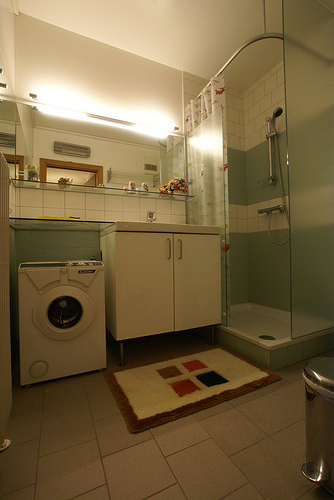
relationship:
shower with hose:
[272, 107, 283, 119] [266, 120, 288, 246]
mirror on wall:
[36, 157, 105, 187] [0, 10, 246, 381]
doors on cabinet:
[117, 232, 225, 343] [97, 221, 222, 364]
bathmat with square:
[101, 345, 283, 434] [197, 365, 227, 386]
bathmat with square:
[101, 345, 283, 434] [169, 373, 200, 396]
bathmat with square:
[101, 345, 283, 434] [155, 361, 181, 380]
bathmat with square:
[101, 345, 283, 434] [182, 353, 207, 372]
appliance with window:
[17, 259, 106, 387] [45, 294, 83, 327]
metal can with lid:
[297, 353, 333, 497] [296, 352, 331, 397]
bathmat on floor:
[101, 334, 283, 434] [4, 341, 332, 498]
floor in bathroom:
[4, 341, 332, 498] [0, 1, 331, 498]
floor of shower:
[227, 311, 311, 340] [181, 43, 333, 371]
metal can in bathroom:
[301, 353, 334, 500] [0, 1, 331, 498]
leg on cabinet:
[115, 342, 130, 367] [99, 221, 221, 367]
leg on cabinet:
[205, 322, 218, 349] [99, 221, 221, 367]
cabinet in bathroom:
[99, 221, 221, 367] [0, 1, 331, 498]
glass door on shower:
[279, 0, 332, 339] [175, 4, 332, 370]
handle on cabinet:
[179, 238, 183, 258] [99, 221, 221, 367]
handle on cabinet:
[165, 238, 172, 258] [99, 221, 221, 367]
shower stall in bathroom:
[182, 30, 332, 372] [0, 1, 331, 498]